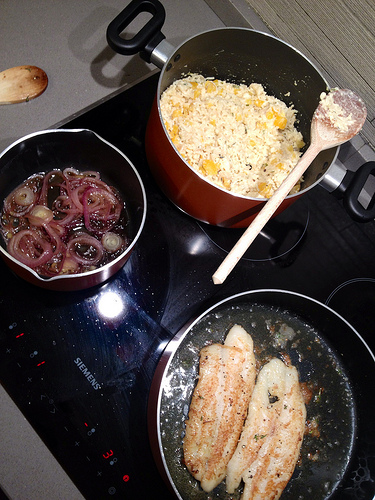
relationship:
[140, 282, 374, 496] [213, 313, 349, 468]
pan has oil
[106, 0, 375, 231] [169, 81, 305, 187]
cook pot has rice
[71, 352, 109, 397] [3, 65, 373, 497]
siemens on stovetop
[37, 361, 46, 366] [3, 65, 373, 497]
number on stovetop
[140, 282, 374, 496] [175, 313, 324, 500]
pan of food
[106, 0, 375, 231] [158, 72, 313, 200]
cook pot of rice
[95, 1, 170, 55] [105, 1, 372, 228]
handle of pot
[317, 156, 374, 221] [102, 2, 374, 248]
handle of cook pot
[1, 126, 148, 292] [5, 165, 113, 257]
pot of onions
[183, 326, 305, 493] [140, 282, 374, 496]
fish in pan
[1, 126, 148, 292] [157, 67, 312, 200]
pot of whatever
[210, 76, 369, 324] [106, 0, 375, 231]
spoon on cook pot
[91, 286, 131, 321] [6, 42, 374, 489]
light reflection reflecting off range top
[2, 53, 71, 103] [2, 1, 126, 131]
spoon on counter top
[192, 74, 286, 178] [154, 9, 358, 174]
rice in pot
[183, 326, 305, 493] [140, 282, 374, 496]
fish in a pan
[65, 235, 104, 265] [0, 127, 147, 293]
onions in a pan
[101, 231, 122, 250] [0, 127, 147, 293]
onions in a pan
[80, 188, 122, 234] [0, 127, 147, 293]
onions in a pan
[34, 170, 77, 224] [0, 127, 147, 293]
onions in a pan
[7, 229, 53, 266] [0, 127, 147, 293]
onions in a pan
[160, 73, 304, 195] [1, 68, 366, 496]
food being prepared on stove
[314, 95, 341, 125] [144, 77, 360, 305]
rice on spoon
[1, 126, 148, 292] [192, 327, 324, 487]
pot simmering food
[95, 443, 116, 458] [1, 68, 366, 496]
number on stove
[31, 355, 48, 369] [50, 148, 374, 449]
number on stove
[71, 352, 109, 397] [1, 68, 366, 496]
siemens on stove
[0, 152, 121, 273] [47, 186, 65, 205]
onions cooking oil